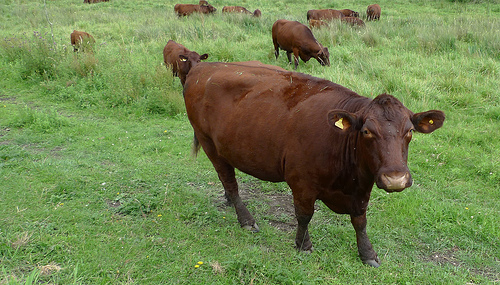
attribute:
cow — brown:
[270, 16, 323, 56]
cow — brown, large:
[261, 17, 337, 72]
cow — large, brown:
[156, 32, 216, 87]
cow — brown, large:
[63, 27, 100, 62]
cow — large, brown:
[365, 4, 385, 31]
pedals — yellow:
[192, 256, 207, 271]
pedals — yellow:
[152, 207, 167, 224]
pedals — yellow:
[217, 209, 228, 224]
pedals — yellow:
[457, 200, 472, 213]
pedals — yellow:
[469, 208, 483, 220]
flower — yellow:
[193, 260, 205, 270]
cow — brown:
[158, 35, 208, 77]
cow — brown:
[360, 7, 390, 29]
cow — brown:
[66, 26, 92, 53]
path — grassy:
[26, 102, 193, 248]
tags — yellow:
[333, 119, 345, 129]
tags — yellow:
[428, 120, 432, 122]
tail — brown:
[187, 131, 203, 161]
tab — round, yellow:
[333, 117, 347, 129]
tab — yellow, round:
[179, 58, 187, 62]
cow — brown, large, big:
[182, 60, 444, 272]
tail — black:
[179, 54, 201, 156]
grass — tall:
[4, 1, 498, 283]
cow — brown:
[285, 77, 453, 251]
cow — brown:
[70, 26, 96, 53]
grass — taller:
[381, 12, 498, 75]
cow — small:
[273, 17, 330, 67]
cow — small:
[368, 4, 382, 21]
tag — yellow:
[335, 116, 345, 128]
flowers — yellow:
[0, 99, 499, 281]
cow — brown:
[271, 20, 330, 70]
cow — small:
[165, 39, 208, 77]